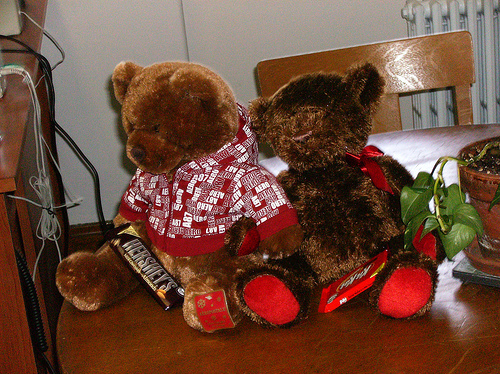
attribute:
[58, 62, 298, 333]
bear — cute, little, plush, furry, brown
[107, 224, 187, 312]
bar — chocolate, hershey's, wrapped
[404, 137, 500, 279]
plant — potted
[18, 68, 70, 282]
cord — long, white, electrical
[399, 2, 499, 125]
radiator — metal, painted, white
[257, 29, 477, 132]
chair — wooden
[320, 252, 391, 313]
bar — kit kat, wrapped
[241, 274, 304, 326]
pads — red, fabric, oval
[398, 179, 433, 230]
leaf — shiny, green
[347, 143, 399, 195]
ribbon — red